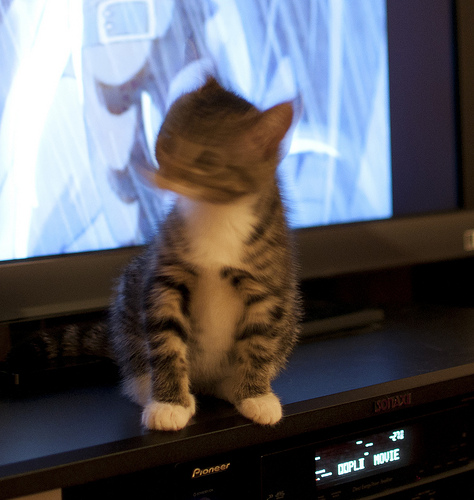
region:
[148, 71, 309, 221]
Blurry face of kitten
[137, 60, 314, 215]
Blurry face of gray kitten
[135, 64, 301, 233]
Blurry face of gray striped kitten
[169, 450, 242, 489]
Silver colored brand of VCR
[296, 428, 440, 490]
Lit VCR lights and indicator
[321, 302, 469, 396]
Brown table holding VCR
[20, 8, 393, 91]
Movie being shown on VCR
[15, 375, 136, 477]
Brown table holding VCR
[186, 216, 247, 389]
White belly of striped kitten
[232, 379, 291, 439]
White paw of striped kitten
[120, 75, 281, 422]
this is a cat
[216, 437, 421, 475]
this is a DVD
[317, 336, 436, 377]
this is a wall unit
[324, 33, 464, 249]
this is a television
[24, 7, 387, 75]
the television is on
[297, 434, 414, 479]
the DVD is on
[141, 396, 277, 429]
the cat's paws are white in color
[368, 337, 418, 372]
the wall unit is wooden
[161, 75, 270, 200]
the cat's head was in motion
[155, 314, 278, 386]
the cat's fur is grey,black and white in color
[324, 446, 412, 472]
letter on a display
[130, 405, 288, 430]
white paws on a cat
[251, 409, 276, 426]
sharp claws on a foor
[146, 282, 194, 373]
black stripes on a leg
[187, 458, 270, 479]
a company name on a VCR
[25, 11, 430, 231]
a tv screen behind a cat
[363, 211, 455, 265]
a plastic gray encasing on a tv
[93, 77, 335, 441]
a kitten shaking his head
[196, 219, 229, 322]
a white patch on a chest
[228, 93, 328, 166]
an ear on a head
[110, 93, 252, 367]
Blurry cat image.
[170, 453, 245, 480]
Pioneer sound system.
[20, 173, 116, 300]
Flat screen television.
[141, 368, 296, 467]
White pawed cat.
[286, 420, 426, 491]
LCD display.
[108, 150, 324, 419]
Cat on the entertainment stand.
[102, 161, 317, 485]
Cat in front of the television.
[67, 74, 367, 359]
Cat in front of TV show.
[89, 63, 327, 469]
Cat on top of the stand.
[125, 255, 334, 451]
Furry cat on the TV stand.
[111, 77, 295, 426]
cat sitting on entertainment center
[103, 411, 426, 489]
pioneer electronics on shelf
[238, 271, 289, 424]
front left leg of cat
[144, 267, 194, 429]
front right leg of cat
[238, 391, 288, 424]
front left paw of cat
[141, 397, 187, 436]
front right paw of cat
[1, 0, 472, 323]
large television behind cat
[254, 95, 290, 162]
left ear of cat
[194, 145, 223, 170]
left eye of cat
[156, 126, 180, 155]
right eye of cat